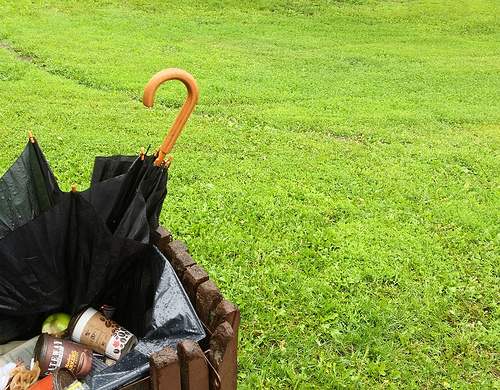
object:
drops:
[16, 213, 24, 223]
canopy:
[6, 130, 176, 326]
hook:
[135, 63, 204, 156]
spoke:
[23, 128, 36, 143]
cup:
[22, 366, 76, 389]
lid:
[50, 364, 77, 389]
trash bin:
[1, 225, 241, 389]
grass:
[0, 1, 499, 389]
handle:
[141, 66, 201, 151]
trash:
[2, 303, 144, 388]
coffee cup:
[66, 302, 139, 360]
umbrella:
[2, 56, 207, 341]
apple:
[37, 309, 75, 334]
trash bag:
[150, 251, 210, 345]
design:
[93, 309, 126, 342]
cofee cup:
[28, 332, 100, 381]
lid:
[30, 328, 49, 369]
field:
[0, 2, 494, 387]